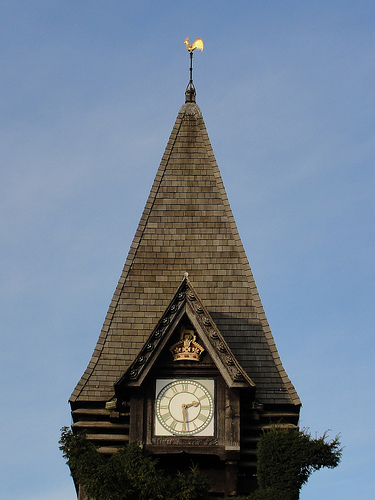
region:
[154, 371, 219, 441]
a clock is on the tower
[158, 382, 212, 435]
the clock has roman numerals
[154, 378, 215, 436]
the clock has a white clockface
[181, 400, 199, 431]
the dials are gold in color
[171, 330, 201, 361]
a crown is above the clock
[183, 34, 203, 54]
a weather vane is above the tower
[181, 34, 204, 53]
the weather vane is painted gold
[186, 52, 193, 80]
the weather vane is on a pole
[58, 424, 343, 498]
the trees are in front of the building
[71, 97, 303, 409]
a hatched roof is on the tower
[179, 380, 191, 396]
roman numeral on clock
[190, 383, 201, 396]
roman numeral on clock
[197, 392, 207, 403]
roman numeral on clock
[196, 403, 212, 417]
roman numeral on clock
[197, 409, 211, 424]
roman numeral on clock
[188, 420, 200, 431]
roman numeral on clock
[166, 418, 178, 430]
roman numeral on clock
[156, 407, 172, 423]
roman numeral on clock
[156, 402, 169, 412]
roman numeral on clock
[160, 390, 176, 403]
roman numeral on clock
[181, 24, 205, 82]
spire of the tower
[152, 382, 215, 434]
clock on the tower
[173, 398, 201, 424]
hands of the clock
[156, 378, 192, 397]
time on the clock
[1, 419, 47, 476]
the sky is clear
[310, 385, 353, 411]
the weather is sunny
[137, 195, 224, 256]
bricks on the roof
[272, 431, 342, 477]
leaves on the towwer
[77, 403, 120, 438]
ridges on the tower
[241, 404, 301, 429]
ridges on the tower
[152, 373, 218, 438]
a clock with the time 3:29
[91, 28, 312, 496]
a wooden clock tower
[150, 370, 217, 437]
a white and gold clock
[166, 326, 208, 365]
a gold crown decoration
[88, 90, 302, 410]
grey roof shingles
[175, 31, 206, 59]
a golden weather mane rooster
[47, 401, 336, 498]
green bushes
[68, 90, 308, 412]
a pointed tower roof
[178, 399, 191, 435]
a gold minutes hand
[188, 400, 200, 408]
a gold hour hand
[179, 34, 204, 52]
golden rooster at top of weather vein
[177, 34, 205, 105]
weather vein at the top of building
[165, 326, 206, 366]
gold crown with red jewels on building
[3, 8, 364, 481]
steeple of brown clock tower building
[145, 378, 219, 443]
white clock with roman numerals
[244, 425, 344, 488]
dark foliage on building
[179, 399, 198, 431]
gold colored clock hands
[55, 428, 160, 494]
dark foliage on clock tower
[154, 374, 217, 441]
face of a clock on building